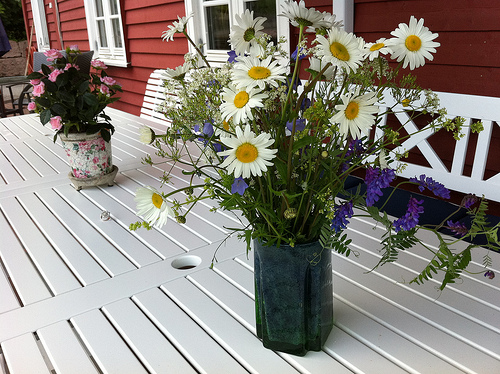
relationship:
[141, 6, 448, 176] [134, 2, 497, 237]
daisies and flowers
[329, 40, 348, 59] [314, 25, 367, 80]
center of daisy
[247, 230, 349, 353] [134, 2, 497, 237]
vase of flowers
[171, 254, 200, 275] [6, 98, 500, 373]
hole in table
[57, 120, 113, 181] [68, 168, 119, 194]
planter on stand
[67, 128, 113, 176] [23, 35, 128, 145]
planter of roses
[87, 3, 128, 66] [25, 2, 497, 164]
window in wall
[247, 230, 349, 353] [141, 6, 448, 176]
vase of daisies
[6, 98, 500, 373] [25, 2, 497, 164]
table by wall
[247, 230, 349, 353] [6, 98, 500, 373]
vase on table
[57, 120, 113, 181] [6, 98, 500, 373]
planter on table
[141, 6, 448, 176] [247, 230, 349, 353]
daisies in vase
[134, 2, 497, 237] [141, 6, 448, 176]
flowers under daisies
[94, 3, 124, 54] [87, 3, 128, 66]
panes in window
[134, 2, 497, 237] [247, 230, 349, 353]
flowers in vase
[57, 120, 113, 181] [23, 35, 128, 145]
planter with roses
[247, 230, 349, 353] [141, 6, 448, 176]
vase has daisies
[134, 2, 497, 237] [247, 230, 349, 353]
flowers hanging from vase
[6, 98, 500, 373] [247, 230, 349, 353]
table holding vase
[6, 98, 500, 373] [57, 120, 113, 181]
table holding planter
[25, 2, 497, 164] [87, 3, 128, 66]
wall with window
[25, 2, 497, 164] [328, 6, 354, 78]
wall with rain gutter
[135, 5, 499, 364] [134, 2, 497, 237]
bouquet of flowers